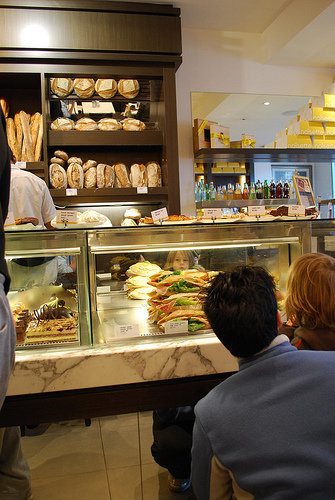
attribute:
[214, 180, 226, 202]
bottle — soda, lined up, on display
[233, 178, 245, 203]
bottle — soda, lined up, on display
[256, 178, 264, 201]
bottle — soda, lined up, on display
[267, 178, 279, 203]
bottle — soda, lined up, on display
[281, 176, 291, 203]
bottle — soda, lined up, on display